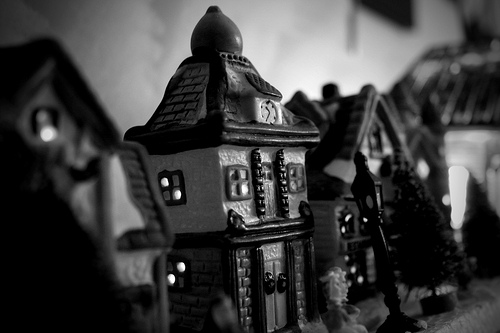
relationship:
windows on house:
[159, 157, 309, 208] [124, 16, 341, 332]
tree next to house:
[387, 151, 465, 315] [124, 16, 341, 332]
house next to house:
[124, 16, 341, 332] [307, 92, 413, 304]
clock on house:
[259, 98, 284, 127] [124, 16, 341, 332]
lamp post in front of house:
[351, 154, 427, 332] [124, 16, 341, 332]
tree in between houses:
[387, 151, 465, 315] [143, 6, 407, 329]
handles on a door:
[265, 270, 285, 295] [264, 260, 293, 332]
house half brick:
[124, 16, 341, 332] [169, 253, 309, 330]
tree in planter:
[387, 151, 465, 315] [423, 286, 453, 318]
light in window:
[160, 177, 185, 203] [157, 169, 190, 212]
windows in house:
[159, 157, 309, 208] [124, 16, 341, 332]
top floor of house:
[133, 134, 309, 223] [124, 16, 341, 332]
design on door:
[265, 270, 287, 293] [264, 260, 293, 332]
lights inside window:
[160, 177, 185, 203] [157, 169, 190, 212]